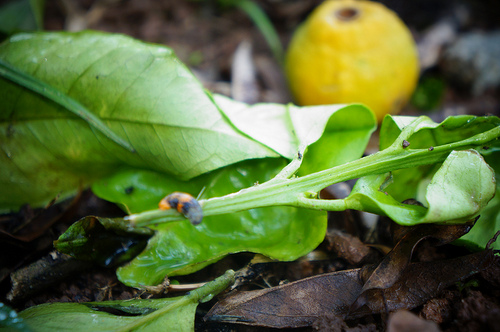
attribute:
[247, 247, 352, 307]
leaves — brown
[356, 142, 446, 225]
leaves — fluffy, green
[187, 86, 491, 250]
leaf — green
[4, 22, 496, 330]
plant — broken off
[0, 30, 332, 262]
leaf — green 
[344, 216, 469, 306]
dead leaf — brown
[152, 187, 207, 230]
bug — orange and black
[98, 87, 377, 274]
leaf — green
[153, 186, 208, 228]
bug — small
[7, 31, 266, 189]
leaf — Green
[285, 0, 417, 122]
lemon — bright yellow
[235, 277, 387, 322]
leaves — brown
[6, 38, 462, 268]
leaves — large, green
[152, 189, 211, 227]
bug/leaf — small, striped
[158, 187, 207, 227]
insect — small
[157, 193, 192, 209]
stripes — black, orange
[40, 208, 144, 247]
stem — broken